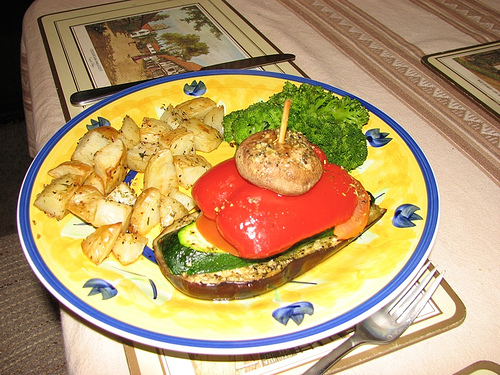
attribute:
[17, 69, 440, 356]
plate — colorful, yellow, blue, filled with food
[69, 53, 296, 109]
knife — on left side, for butter, silver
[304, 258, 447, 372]
fork — on the right side, silver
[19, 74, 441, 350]
border — blue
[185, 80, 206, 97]
flower — blue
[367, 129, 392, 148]
flower — blue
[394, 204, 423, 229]
flower — blue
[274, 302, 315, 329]
flower — blue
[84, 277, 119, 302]
flower — blue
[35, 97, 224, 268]
potatoes — fried, spicy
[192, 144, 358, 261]
pepper — red, sliced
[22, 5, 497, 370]
tablecloth — designed, southwestern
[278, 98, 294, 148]
stick — holding food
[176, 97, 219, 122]
potato — sliced, seasoned, roasted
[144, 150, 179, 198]
potato — sliced up, seasoned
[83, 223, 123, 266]
potato — sliced up, seasoned, roasted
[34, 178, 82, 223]
potato — sliced up, seasoned, roasted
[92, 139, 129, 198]
potato — sliced up, seasoned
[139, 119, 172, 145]
potato — sliced up, seasoned, roasted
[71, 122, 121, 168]
potato — sliced up, seasoned, roasted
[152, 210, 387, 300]
eggplant — a slice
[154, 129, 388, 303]
sandwich — vegetables